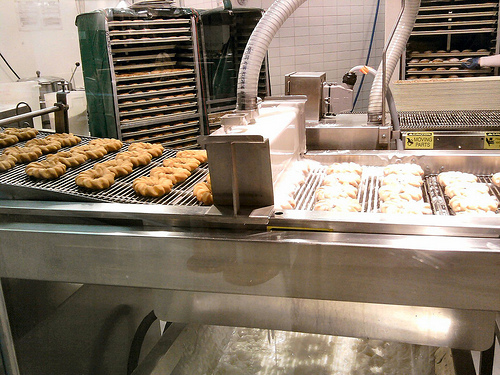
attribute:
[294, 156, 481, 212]
donuts — uncooked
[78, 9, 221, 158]
donut cart — green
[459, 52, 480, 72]
glove — black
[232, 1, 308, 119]
tube — large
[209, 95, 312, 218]
section — large, metal, rectangular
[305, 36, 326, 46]
tile — white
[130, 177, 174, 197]
donut — plain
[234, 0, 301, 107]
tube — flexible, plastic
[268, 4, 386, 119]
wall — white, tile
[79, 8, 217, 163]
rack — tall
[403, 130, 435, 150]
sticker — yellow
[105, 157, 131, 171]
doughnut — fresh, warm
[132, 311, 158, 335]
hose — black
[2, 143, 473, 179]
conveyor belt — metal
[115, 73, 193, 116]
trays — stacked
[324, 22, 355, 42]
tiles — white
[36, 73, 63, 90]
container — metal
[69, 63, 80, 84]
handle — metal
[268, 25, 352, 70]
wall — white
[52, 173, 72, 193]
rollers — little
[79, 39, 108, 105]
cover — green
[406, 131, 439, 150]
sticker — yellow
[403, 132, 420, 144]
writing — black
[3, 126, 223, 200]
six lines — of doughnuts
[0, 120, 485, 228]
metal-conveyor belt — with doughnuts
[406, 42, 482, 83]
doughnuts — with white frosting